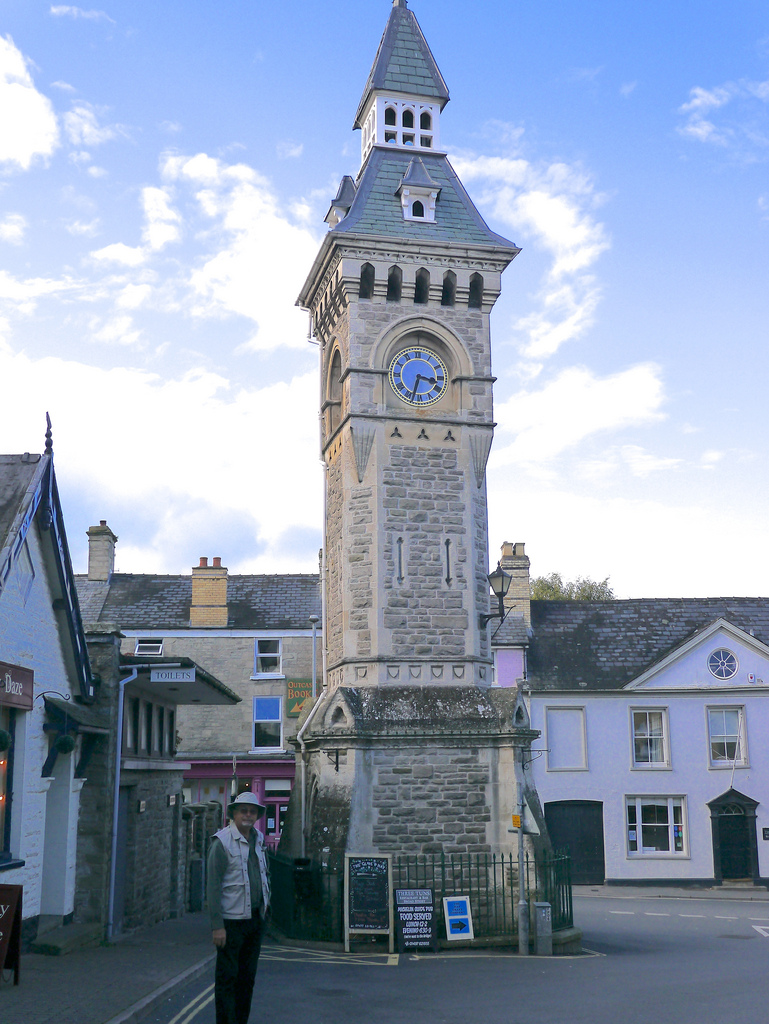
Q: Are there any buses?
A: No, there are no buses.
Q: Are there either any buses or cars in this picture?
A: No, there are no buses or cars.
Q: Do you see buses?
A: No, there are no buses.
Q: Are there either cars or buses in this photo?
A: No, there are no buses or cars.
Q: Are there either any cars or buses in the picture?
A: No, there are no cars or buses.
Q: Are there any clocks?
A: Yes, there is a clock.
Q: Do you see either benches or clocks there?
A: Yes, there is a clock.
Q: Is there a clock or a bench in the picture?
A: Yes, there is a clock.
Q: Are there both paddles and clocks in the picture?
A: No, there is a clock but no paddles.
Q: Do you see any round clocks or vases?
A: Yes, there is a round clock.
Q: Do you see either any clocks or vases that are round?
A: Yes, the clock is round.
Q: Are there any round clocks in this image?
A: Yes, there is a round clock.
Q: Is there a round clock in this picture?
A: Yes, there is a round clock.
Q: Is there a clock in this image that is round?
A: Yes, there is a clock that is round.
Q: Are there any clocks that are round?
A: Yes, there is a clock that is round.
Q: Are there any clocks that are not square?
A: Yes, there is a round clock.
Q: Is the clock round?
A: Yes, the clock is round.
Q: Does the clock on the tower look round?
A: Yes, the clock is round.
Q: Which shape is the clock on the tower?
A: The clock is round.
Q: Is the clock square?
A: No, the clock is round.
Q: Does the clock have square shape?
A: No, the clock is round.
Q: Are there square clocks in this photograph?
A: No, there is a clock but it is round.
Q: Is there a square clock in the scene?
A: No, there is a clock but it is round.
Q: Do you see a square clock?
A: No, there is a clock but it is round.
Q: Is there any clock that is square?
A: No, there is a clock but it is round.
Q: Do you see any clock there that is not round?
A: No, there is a clock but it is round.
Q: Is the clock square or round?
A: The clock is round.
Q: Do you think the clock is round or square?
A: The clock is round.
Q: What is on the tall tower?
A: The clock is on the tower.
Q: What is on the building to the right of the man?
A: The clock is on the tower.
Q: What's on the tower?
A: The clock is on the tower.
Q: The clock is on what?
A: The clock is on the tower.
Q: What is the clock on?
A: The clock is on the tower.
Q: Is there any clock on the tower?
A: Yes, there is a clock on the tower.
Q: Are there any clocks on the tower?
A: Yes, there is a clock on the tower.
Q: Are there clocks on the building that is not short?
A: Yes, there is a clock on the tower.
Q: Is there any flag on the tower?
A: No, there is a clock on the tower.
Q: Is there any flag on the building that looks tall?
A: No, there is a clock on the tower.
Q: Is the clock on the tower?
A: Yes, the clock is on the tower.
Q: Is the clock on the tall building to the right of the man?
A: Yes, the clock is on the tower.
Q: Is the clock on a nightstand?
A: No, the clock is on the tower.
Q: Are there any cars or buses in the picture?
A: No, there are no cars or buses.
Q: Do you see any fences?
A: Yes, there is a fence.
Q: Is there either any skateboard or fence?
A: Yes, there is a fence.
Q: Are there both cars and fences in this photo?
A: No, there is a fence but no cars.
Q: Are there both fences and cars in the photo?
A: No, there is a fence but no cars.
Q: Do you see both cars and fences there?
A: No, there is a fence but no cars.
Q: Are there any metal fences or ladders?
A: Yes, there is a metal fence.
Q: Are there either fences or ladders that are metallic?
A: Yes, the fence is metallic.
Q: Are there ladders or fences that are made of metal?
A: Yes, the fence is made of metal.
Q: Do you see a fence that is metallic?
A: Yes, there is a metal fence.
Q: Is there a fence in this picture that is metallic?
A: Yes, there is a fence that is metallic.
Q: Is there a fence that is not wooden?
A: Yes, there is a metallic fence.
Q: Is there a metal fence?
A: Yes, there is a fence that is made of metal.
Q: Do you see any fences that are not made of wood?
A: Yes, there is a fence that is made of metal.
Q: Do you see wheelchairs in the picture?
A: No, there are no wheelchairs.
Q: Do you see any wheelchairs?
A: No, there are no wheelchairs.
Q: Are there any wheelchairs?
A: No, there are no wheelchairs.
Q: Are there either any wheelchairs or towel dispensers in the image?
A: No, there are no wheelchairs or towel dispensers.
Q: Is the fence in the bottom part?
A: Yes, the fence is in the bottom of the image.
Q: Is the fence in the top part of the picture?
A: No, the fence is in the bottom of the image.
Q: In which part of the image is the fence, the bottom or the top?
A: The fence is in the bottom of the image.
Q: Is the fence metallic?
A: Yes, the fence is metallic.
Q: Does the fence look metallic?
A: Yes, the fence is metallic.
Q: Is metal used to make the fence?
A: Yes, the fence is made of metal.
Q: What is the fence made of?
A: The fence is made of metal.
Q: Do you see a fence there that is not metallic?
A: No, there is a fence but it is metallic.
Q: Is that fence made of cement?
A: No, the fence is made of metal.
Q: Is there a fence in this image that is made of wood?
A: No, there is a fence but it is made of metal.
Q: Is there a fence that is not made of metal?
A: No, there is a fence but it is made of metal.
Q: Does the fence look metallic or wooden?
A: The fence is metallic.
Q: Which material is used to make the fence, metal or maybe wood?
A: The fence is made of metal.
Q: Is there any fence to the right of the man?
A: Yes, there is a fence to the right of the man.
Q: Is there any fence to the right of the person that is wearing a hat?
A: Yes, there is a fence to the right of the man.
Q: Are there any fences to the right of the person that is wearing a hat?
A: Yes, there is a fence to the right of the man.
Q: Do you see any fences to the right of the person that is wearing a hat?
A: Yes, there is a fence to the right of the man.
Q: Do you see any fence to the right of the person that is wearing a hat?
A: Yes, there is a fence to the right of the man.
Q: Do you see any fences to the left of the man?
A: No, the fence is to the right of the man.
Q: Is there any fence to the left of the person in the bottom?
A: No, the fence is to the right of the man.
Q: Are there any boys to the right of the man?
A: No, there is a fence to the right of the man.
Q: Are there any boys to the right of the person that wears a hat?
A: No, there is a fence to the right of the man.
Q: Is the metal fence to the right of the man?
A: Yes, the fence is to the right of the man.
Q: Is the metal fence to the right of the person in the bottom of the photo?
A: Yes, the fence is to the right of the man.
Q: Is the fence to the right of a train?
A: No, the fence is to the right of the man.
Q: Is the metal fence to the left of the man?
A: No, the fence is to the right of the man.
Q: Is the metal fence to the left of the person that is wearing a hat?
A: No, the fence is to the right of the man.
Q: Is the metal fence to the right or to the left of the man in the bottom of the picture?
A: The fence is to the right of the man.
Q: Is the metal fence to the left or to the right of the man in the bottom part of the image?
A: The fence is to the right of the man.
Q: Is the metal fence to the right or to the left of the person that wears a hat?
A: The fence is to the right of the man.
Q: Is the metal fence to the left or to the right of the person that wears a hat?
A: The fence is to the right of the man.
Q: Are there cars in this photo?
A: No, there are no cars.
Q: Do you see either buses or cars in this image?
A: No, there are no cars or buses.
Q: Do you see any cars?
A: No, there are no cars.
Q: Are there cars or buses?
A: No, there are no cars or buses.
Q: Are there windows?
A: Yes, there is a window.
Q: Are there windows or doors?
A: Yes, there is a window.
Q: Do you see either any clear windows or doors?
A: Yes, there is a clear window.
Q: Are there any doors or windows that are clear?
A: Yes, the window is clear.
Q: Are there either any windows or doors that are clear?
A: Yes, the window is clear.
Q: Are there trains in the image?
A: No, there are no trains.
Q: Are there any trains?
A: No, there are no trains.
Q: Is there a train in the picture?
A: No, there are no trains.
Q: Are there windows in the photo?
A: Yes, there is a window.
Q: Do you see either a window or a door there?
A: Yes, there is a window.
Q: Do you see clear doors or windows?
A: Yes, there is a clear window.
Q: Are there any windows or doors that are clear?
A: Yes, the window is clear.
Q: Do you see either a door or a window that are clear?
A: Yes, the window is clear.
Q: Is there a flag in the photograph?
A: No, there are no flags.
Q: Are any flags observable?
A: No, there are no flags.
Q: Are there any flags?
A: No, there are no flags.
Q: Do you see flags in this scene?
A: No, there are no flags.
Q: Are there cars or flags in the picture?
A: No, there are no flags or cars.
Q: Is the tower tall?
A: Yes, the tower is tall.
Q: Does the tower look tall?
A: Yes, the tower is tall.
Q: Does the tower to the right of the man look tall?
A: Yes, the tower is tall.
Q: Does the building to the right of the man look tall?
A: Yes, the tower is tall.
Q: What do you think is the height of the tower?
A: The tower is tall.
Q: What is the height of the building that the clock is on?
A: The tower is tall.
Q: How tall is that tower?
A: The tower is tall.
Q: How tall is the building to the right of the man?
A: The tower is tall.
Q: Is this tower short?
A: No, the tower is tall.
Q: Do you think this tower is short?
A: No, the tower is tall.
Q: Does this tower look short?
A: No, the tower is tall.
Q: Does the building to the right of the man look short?
A: No, the tower is tall.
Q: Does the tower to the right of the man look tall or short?
A: The tower is tall.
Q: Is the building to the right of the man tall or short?
A: The tower is tall.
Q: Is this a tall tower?
A: Yes, this is a tall tower.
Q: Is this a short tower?
A: No, this is a tall tower.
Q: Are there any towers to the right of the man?
A: Yes, there is a tower to the right of the man.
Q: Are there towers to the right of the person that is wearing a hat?
A: Yes, there is a tower to the right of the man.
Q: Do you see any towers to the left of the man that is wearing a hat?
A: No, the tower is to the right of the man.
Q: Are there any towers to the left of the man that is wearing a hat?
A: No, the tower is to the right of the man.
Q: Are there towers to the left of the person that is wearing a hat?
A: No, the tower is to the right of the man.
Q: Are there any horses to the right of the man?
A: No, there is a tower to the right of the man.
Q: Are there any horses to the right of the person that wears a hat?
A: No, there is a tower to the right of the man.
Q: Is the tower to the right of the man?
A: Yes, the tower is to the right of the man.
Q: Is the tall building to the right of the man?
A: Yes, the tower is to the right of the man.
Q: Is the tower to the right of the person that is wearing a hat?
A: Yes, the tower is to the right of the man.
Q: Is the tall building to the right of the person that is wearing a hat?
A: Yes, the tower is to the right of the man.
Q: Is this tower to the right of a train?
A: No, the tower is to the right of the man.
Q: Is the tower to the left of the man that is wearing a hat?
A: No, the tower is to the right of the man.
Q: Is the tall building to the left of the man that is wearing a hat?
A: No, the tower is to the right of the man.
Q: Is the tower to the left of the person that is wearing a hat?
A: No, the tower is to the right of the man.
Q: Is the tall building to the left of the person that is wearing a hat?
A: No, the tower is to the right of the man.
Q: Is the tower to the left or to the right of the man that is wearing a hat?
A: The tower is to the right of the man.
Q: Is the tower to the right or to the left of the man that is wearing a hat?
A: The tower is to the right of the man.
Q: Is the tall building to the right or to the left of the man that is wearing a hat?
A: The tower is to the right of the man.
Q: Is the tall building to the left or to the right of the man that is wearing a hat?
A: The tower is to the right of the man.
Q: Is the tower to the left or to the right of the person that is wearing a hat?
A: The tower is to the right of the man.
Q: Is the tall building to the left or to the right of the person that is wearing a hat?
A: The tower is to the right of the man.